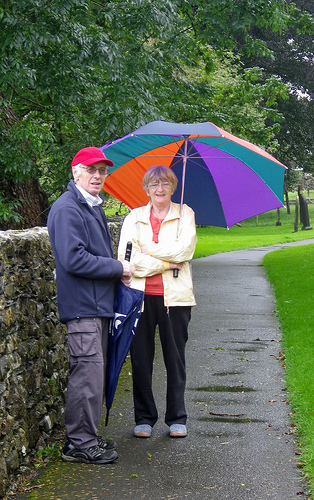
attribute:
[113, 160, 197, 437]
woman — holding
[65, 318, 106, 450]
pants — grey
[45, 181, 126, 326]
jacket — blue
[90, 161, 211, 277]
woman — wearing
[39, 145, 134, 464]
man — wearing